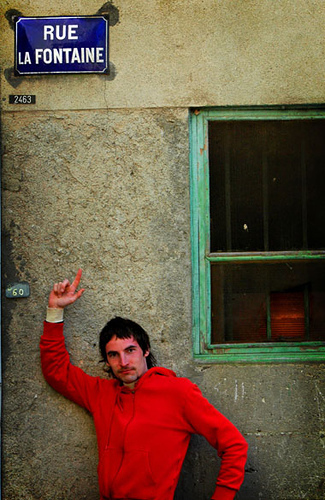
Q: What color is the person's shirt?
A: Red.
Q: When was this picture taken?
A: During the day.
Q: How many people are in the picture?
A: One.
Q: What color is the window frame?
A: Green.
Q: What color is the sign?
A: Blue.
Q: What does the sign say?
A: Rue La Fontaine.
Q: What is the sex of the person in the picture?
A: Male.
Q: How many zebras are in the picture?
A: Zero.